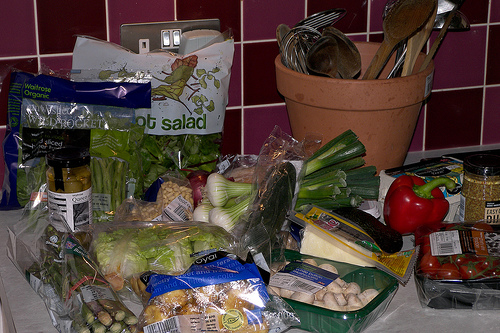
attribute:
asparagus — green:
[26, 226, 139, 331]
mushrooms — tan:
[262, 248, 399, 331]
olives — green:
[38, 146, 104, 247]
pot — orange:
[271, 37, 438, 171]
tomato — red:
[439, 262, 461, 279]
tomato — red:
[420, 253, 438, 275]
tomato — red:
[461, 259, 481, 279]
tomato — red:
[480, 256, 496, 271]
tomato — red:
[455, 252, 473, 266]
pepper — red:
[383, 171, 455, 236]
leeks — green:
[191, 128, 381, 231]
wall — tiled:
[3, 9, 498, 198]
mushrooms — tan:
[262, 255, 400, 327]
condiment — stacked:
[460, 151, 497, 227]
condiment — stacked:
[37, 145, 101, 240]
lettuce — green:
[91, 213, 238, 290]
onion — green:
[188, 170, 234, 207]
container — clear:
[117, 80, 474, 289]